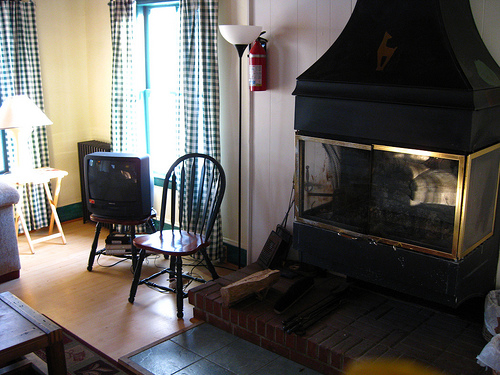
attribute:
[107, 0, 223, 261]
curtains — long , blue and white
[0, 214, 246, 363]
floor — light-colored, wood 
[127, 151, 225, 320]
chair — wooden , black and brown, brown 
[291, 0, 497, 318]
fireplace — huge , black and gold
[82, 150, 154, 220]
tv set — black, small 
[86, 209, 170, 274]
stool — black and brown, wooden 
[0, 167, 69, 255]
folding table — brown 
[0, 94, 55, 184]
table lamp — short 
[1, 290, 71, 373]
table — brown 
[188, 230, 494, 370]
hearth — red 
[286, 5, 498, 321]
fire place — black 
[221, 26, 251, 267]
lamp — black 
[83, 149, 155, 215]
tv — small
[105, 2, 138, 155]
curtain — plaid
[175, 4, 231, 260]
curtain — plaid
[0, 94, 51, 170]
lamp — white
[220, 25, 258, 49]
light — white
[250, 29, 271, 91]
extinguisher — red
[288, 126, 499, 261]
enclosure — black and gold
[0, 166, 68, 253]
table — open , small 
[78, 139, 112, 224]
heater — black 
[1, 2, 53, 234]
curtain — blue and white, plaid, Green and white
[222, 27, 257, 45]
shade — white 